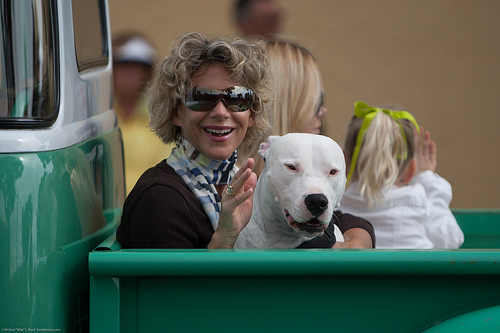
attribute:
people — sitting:
[125, 39, 439, 239]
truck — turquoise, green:
[3, 0, 499, 329]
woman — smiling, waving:
[125, 38, 376, 246]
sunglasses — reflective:
[182, 89, 257, 109]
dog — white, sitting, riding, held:
[241, 134, 355, 251]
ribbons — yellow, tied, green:
[345, 103, 425, 185]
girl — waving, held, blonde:
[341, 100, 471, 257]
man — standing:
[232, 4, 299, 37]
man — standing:
[116, 34, 178, 198]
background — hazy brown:
[73, 4, 499, 187]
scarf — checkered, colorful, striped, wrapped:
[169, 136, 246, 225]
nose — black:
[305, 194, 327, 218]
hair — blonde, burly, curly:
[145, 41, 272, 141]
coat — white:
[348, 173, 467, 252]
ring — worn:
[228, 183, 236, 197]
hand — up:
[414, 127, 439, 178]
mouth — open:
[279, 203, 333, 236]